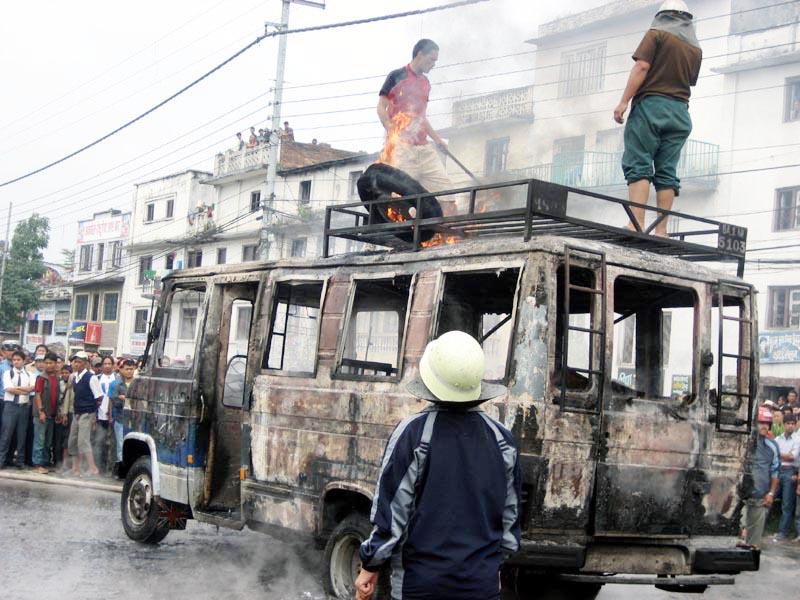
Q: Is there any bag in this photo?
A: No, there are no bags.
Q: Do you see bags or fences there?
A: No, there are no bags or fences.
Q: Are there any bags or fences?
A: No, there are no bags or fences.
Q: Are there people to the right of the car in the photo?
A: No, the person is to the left of the car.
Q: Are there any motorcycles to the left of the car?
A: No, there is a person to the left of the car.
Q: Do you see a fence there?
A: No, there are no fences.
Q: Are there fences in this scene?
A: No, there are no fences.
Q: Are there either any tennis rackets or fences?
A: No, there are no fences or tennis rackets.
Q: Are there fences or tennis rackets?
A: No, there are no fences or tennis rackets.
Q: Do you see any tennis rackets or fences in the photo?
A: No, there are no fences or tennis rackets.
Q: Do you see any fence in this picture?
A: No, there are no fences.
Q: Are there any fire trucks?
A: No, there are no fire trucks.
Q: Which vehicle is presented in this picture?
A: The vehicle is a car.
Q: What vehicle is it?
A: The vehicle is a car.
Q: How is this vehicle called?
A: This is a car.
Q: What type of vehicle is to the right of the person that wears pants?
A: The vehicle is a car.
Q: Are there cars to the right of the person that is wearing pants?
A: Yes, there is a car to the right of the person.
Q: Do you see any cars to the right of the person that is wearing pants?
A: Yes, there is a car to the right of the person.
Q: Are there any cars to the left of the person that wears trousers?
A: No, the car is to the right of the person.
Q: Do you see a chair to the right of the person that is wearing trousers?
A: No, there is a car to the right of the person.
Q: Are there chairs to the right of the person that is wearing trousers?
A: No, there is a car to the right of the person.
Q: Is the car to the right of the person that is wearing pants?
A: Yes, the car is to the right of the person.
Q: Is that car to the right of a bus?
A: No, the car is to the right of the person.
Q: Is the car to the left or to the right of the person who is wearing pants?
A: The car is to the right of the person.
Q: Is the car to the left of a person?
A: No, the car is to the right of a person.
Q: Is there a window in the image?
A: Yes, there is a window.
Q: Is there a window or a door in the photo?
A: Yes, there is a window.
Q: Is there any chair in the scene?
A: No, there are no chairs.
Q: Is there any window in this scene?
A: Yes, there is a window.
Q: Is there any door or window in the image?
A: Yes, there is a window.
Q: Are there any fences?
A: No, there are no fences.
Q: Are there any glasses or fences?
A: No, there are no fences or glasses.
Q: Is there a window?
A: Yes, there is a window.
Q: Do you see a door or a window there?
A: Yes, there is a window.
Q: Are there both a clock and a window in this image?
A: No, there is a window but no clocks.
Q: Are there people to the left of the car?
A: Yes, there is a person to the left of the car.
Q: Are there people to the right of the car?
A: No, the person is to the left of the car.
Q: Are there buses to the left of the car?
A: No, there is a person to the left of the car.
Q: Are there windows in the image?
A: Yes, there is a window.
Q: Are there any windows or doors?
A: Yes, there is a window.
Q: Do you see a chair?
A: No, there are no chairs.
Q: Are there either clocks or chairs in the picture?
A: No, there are no chairs or clocks.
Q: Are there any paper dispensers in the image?
A: No, there are no paper dispensers.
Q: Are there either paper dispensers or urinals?
A: No, there are no paper dispensers or urinals.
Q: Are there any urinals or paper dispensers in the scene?
A: No, there are no paper dispensers or urinals.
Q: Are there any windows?
A: Yes, there is a window.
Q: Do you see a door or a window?
A: Yes, there is a window.